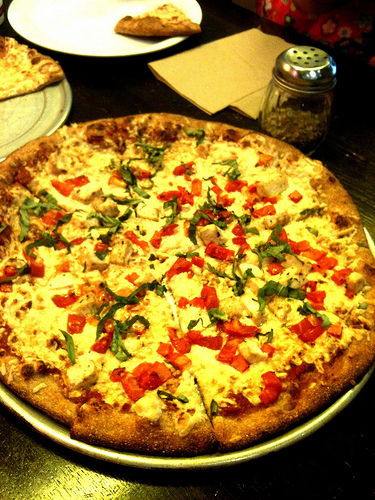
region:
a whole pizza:
[108, 200, 247, 368]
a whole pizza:
[121, 240, 257, 486]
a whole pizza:
[90, 225, 204, 484]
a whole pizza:
[121, 263, 213, 438]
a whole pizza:
[145, 263, 215, 361]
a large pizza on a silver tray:
[2, 120, 373, 472]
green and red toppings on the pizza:
[159, 167, 204, 226]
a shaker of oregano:
[251, 33, 342, 157]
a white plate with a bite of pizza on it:
[8, 0, 205, 63]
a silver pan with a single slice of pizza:
[1, 30, 76, 162]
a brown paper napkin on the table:
[149, 13, 307, 130]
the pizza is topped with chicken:
[248, 166, 294, 213]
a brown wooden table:
[2, 433, 75, 498]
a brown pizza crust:
[107, 7, 210, 45]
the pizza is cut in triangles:
[59, 266, 231, 461]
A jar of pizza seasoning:
[252, 30, 346, 143]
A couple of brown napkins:
[144, 23, 298, 115]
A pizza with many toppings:
[3, 93, 371, 499]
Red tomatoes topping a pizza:
[120, 364, 181, 397]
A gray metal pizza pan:
[3, 76, 76, 153]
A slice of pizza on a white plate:
[105, 5, 207, 45]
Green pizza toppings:
[102, 287, 156, 313]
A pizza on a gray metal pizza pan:
[2, 94, 373, 476]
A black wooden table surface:
[9, 450, 70, 493]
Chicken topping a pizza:
[343, 271, 366, 298]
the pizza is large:
[41, 206, 335, 431]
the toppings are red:
[106, 283, 220, 352]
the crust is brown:
[90, 420, 234, 456]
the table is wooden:
[93, 77, 159, 98]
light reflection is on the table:
[50, 471, 112, 496]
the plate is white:
[11, 9, 140, 59]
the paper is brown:
[161, 53, 261, 111]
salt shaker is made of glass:
[268, 51, 343, 143]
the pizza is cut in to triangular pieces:
[3, 129, 373, 435]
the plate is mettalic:
[17, 95, 95, 121]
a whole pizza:
[153, 336, 257, 480]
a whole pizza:
[117, 318, 167, 372]